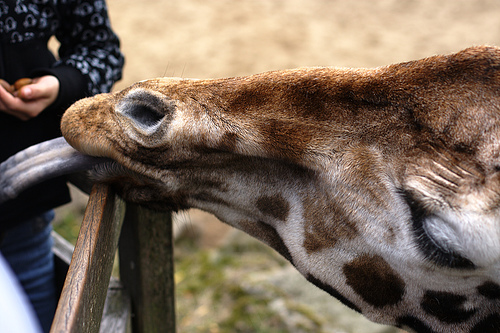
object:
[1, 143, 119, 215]
tongue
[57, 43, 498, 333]
giraffe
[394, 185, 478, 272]
eye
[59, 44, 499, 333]
face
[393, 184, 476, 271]
lashes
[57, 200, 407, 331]
grass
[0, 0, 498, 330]
zoo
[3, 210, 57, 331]
jeans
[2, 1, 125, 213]
sweater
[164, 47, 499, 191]
forehead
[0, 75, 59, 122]
hand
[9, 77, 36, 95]
food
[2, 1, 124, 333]
person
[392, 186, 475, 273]
eyelashes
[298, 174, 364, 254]
spot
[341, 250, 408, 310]
spot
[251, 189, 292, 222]
spot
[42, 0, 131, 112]
sleeve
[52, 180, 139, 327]
wood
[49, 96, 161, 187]
mouth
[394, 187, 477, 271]
eyeball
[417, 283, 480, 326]
spot